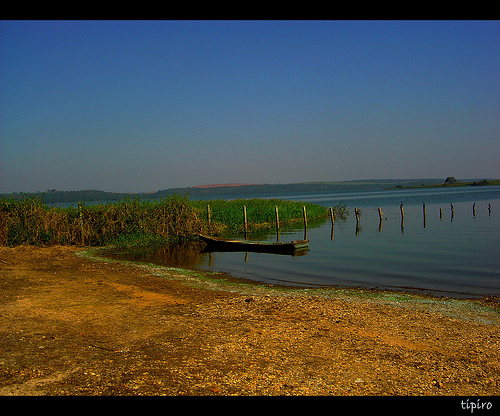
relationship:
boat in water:
[208, 229, 313, 261] [334, 228, 418, 271]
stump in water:
[371, 206, 393, 226] [334, 228, 418, 271]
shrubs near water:
[85, 208, 130, 227] [334, 228, 418, 271]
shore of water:
[90, 274, 268, 365] [334, 228, 418, 271]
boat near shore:
[208, 229, 313, 261] [90, 274, 268, 365]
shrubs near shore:
[85, 208, 130, 227] [90, 274, 268, 365]